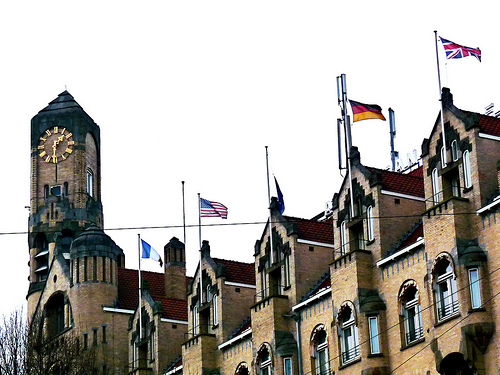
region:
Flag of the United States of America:
[195, 193, 230, 223]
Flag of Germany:
[342, 93, 385, 123]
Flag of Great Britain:
[433, 25, 483, 61]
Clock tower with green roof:
[23, 84, 106, 372]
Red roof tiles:
[157, 296, 197, 323]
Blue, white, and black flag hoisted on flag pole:
[134, 228, 166, 308]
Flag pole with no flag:
[262, 140, 279, 265]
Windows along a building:
[171, 251, 493, 373]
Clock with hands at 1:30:
[30, 121, 79, 167]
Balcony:
[247, 234, 294, 308]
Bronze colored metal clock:
[36, 122, 74, 163]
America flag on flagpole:
[192, 192, 231, 216]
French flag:
[132, 236, 169, 264]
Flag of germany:
[339, 93, 391, 123]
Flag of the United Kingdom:
[429, 30, 486, 67]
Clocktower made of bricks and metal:
[23, 75, 104, 223]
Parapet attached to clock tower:
[67, 221, 117, 284]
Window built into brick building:
[335, 317, 385, 356]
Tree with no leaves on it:
[0, 316, 109, 369]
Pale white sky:
[75, 33, 304, 88]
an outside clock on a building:
[18, 60, 130, 373]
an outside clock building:
[14, 48, 127, 330]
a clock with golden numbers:
[7, 73, 124, 294]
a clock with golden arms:
[9, 70, 143, 260]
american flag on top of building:
[179, 168, 254, 319]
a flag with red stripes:
[179, 182, 242, 271]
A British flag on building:
[415, 7, 499, 151]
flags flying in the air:
[94, 10, 499, 287]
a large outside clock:
[8, 53, 139, 265]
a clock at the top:
[4, 50, 129, 271]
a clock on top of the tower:
[34, 125, 76, 165]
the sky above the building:
[11, 5, 487, 215]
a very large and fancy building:
[19, 74, 486, 371]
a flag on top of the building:
[348, 95, 387, 125]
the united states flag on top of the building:
[198, 195, 228, 221]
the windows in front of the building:
[243, 243, 489, 372]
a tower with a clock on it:
[26, 92, 106, 240]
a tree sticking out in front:
[1, 309, 114, 372]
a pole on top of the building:
[331, 74, 358, 171]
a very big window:
[38, 291, 82, 337]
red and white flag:
[177, 175, 234, 275]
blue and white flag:
[116, 224, 175, 293]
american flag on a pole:
[181, 178, 236, 261]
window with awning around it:
[417, 247, 464, 351]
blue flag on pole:
[231, 136, 295, 257]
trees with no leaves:
[0, 310, 102, 373]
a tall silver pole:
[164, 161, 192, 271]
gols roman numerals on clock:
[30, 125, 75, 164]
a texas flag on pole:
[414, 17, 480, 119]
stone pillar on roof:
[161, 217, 188, 317]